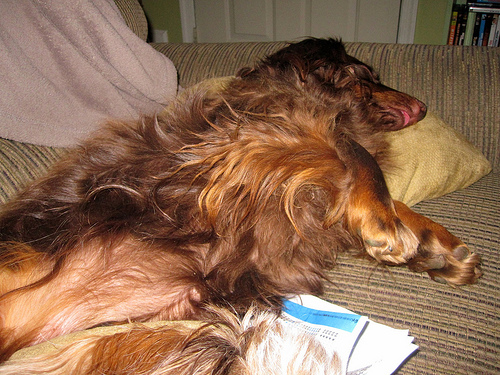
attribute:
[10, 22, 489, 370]
dog — sleeping, hairy, brown, furry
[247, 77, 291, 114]
hair — orange red, long, gold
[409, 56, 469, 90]
couch — brown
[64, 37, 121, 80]
blanket — draped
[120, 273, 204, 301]
belly — pink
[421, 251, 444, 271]
paw pads — brown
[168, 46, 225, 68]
sofa — brown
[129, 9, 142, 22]
fabric — striped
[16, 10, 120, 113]
towel — pink, beige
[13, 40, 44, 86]
cloth — pink, rumpled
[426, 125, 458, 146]
cushion — golden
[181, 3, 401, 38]
door — closed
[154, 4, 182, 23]
wall — gree